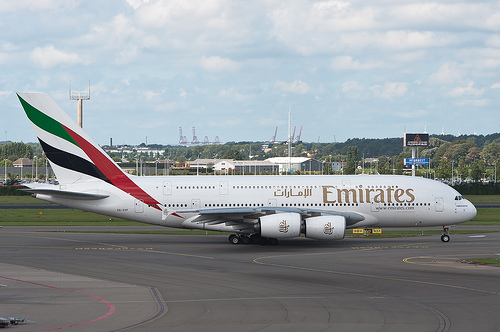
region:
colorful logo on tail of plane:
[24, 108, 155, 197]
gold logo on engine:
[268, 219, 300, 236]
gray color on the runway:
[137, 249, 264, 291]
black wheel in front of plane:
[423, 228, 467, 244]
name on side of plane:
[316, 179, 428, 206]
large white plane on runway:
[23, 95, 477, 265]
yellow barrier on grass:
[353, 223, 398, 238]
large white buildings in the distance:
[187, 146, 299, 173]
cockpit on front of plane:
[450, 182, 471, 202]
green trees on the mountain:
[393, 128, 474, 169]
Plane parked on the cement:
[14, 81, 497, 279]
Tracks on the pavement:
[198, 245, 301, 330]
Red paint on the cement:
[57, 263, 143, 315]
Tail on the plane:
[12, 85, 154, 260]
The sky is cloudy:
[129, 8, 306, 95]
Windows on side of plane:
[245, 172, 413, 238]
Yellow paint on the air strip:
[377, 230, 462, 275]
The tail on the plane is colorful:
[17, 103, 149, 226]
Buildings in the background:
[164, 131, 377, 173]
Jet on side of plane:
[240, 208, 318, 250]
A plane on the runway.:
[24, 106, 479, 264]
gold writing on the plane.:
[314, 179, 427, 199]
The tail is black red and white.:
[25, 91, 107, 173]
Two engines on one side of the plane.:
[260, 208, 355, 240]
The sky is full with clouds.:
[153, 61, 393, 117]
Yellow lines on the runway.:
[55, 222, 137, 267]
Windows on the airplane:
[168, 178, 268, 199]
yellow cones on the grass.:
[350, 225, 392, 237]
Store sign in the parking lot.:
[400, 130, 437, 159]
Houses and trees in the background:
[118, 142, 183, 159]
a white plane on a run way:
[17, 83, 475, 250]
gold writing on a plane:
[279, 183, 418, 203]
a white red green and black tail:
[16, 88, 126, 217]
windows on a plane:
[178, 181, 283, 191]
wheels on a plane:
[435, 231, 451, 241]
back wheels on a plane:
[225, 235, 271, 247]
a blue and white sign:
[397, 156, 427, 162]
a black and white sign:
[406, 135, 426, 145]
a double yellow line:
[393, 244, 430, 271]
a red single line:
[71, 276, 133, 328]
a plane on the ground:
[62, 76, 497, 322]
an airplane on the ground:
[94, 31, 437, 326]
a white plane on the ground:
[140, 107, 496, 329]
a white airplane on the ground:
[153, 116, 415, 287]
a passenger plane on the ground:
[118, 98, 487, 317]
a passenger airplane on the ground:
[104, 66, 497, 308]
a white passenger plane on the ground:
[125, 76, 483, 303]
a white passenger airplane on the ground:
[22, 86, 390, 326]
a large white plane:
[122, 68, 495, 287]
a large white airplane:
[100, 106, 476, 223]